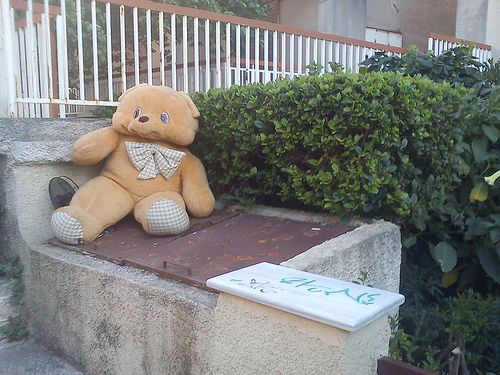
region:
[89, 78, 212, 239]
Giant teddy bear is brown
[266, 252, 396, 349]
Grafitti beside bear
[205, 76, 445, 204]
Shrubs behind bear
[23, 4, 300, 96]
White fence near hedge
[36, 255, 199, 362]
Concrete wall near stairs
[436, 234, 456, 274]
Leaf of bush is green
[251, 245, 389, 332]
Rectangular tile on shelf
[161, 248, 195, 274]
Rusty red handle near bear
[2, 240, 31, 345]
Small green plants growing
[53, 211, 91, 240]
Bear's foot is white and brown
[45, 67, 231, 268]
Light brown teddy bear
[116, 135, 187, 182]
Bow on teddy bears neck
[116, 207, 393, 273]
Metal door mounted on concrete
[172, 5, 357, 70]
White and brown rails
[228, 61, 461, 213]
Green shrubbery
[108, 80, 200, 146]
Teddy bears head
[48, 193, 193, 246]
Gingham fabric on a teddy bears feet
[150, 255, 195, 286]
Handle on metal door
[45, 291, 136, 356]
Grey colored concrete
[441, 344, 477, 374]
Limbs on shrubbery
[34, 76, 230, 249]
A teddy bear is in the foreground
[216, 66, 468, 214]
A green bush is in the foreground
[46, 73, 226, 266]
Teddy bear is light brown in color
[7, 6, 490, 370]
Photo was taken outside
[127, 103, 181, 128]
Teddy bear's eyes are brown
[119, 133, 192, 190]
Stuffed animal is wearing a bow tie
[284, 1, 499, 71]
A building is in the backgrond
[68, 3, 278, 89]
A tree is in the background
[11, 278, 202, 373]
A small concrete wall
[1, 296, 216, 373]
Concrete is light gray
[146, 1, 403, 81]
A guardrail.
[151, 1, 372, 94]
The guard rail is brown and white.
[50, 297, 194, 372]
The stone is gray.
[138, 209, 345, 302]
A rusted lid.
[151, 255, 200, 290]
The lid has a handle.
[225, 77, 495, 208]
A plant.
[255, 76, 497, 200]
The plant has leaves on it.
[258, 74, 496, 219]
The plant is green.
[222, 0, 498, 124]
A building is in the background.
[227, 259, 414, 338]
Graffiti.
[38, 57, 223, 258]
A brown teddy bear with a bow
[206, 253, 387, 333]
Green and black graffiti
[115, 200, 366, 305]
A brown rusty lid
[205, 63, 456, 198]
A bush with green leaves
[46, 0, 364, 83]
A brown and white fence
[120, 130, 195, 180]
A bow on a teddy bear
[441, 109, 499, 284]
Green leaves on a bush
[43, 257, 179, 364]
A gray concrete wall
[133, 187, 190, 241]
A teddy bear's foot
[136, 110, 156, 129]
A teddy bear's nose